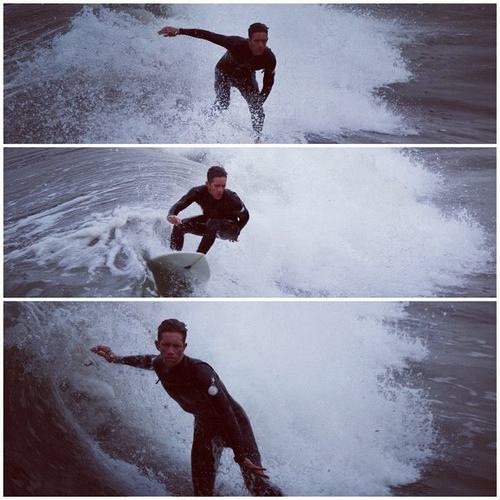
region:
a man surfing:
[112, 9, 441, 139]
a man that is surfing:
[115, 157, 499, 400]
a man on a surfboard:
[96, 326, 396, 496]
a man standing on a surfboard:
[89, 302, 397, 493]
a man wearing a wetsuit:
[122, 316, 326, 490]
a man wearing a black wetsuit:
[117, 298, 379, 498]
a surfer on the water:
[85, 318, 318, 469]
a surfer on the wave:
[75, 305, 367, 497]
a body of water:
[48, 309, 330, 489]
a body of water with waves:
[42, 323, 279, 485]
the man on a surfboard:
[148, 165, 248, 284]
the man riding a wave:
[145, 163, 250, 286]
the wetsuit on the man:
[165, 183, 247, 253]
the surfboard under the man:
[150, 251, 210, 286]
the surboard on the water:
[152, 251, 209, 287]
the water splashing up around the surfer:
[3, 3, 417, 143]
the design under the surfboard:
[184, 253, 204, 270]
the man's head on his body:
[205, 164, 227, 201]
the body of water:
[4, 148, 499, 299]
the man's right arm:
[90, 343, 160, 370]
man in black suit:
[133, 315, 278, 466]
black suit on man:
[163, 342, 260, 444]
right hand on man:
[93, 348, 161, 388]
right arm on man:
[77, 342, 185, 399]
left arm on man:
[204, 394, 275, 476]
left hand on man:
[229, 454, 276, 488]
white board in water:
[134, 245, 262, 290]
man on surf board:
[156, 170, 278, 318]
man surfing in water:
[139, 163, 319, 292]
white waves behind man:
[123, 320, 387, 448]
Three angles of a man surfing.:
[5, 10, 485, 495]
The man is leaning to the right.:
[155, 21, 276, 142]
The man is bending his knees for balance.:
[165, 165, 247, 251]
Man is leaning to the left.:
[87, 317, 277, 493]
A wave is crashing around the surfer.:
[7, 0, 407, 142]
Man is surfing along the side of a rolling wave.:
[1, 150, 298, 295]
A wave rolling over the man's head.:
[21, 300, 436, 495]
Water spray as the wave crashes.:
[55, 5, 407, 135]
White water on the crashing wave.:
[50, 146, 485, 291]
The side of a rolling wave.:
[37, 301, 210, 492]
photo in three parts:
[23, 10, 461, 492]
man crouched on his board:
[140, 151, 270, 291]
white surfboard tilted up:
[150, 250, 210, 290]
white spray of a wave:
[277, 152, 442, 287]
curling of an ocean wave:
[131, 146, 203, 176]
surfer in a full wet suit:
[87, 312, 289, 492]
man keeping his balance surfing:
[110, 5, 330, 140]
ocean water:
[351, 10, 496, 490]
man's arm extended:
[71, 316, 193, 376]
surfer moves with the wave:
[108, 153, 278, 285]